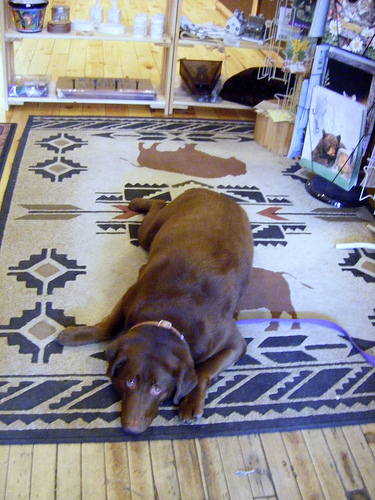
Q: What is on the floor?
A: Rug.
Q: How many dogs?
A: 1.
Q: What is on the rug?
A: Dog.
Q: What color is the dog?
A: Brown.